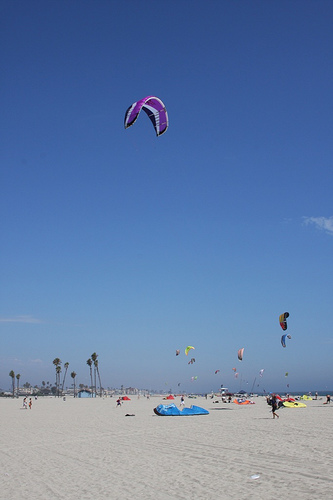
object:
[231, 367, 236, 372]
kites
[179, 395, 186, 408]
person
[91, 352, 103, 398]
tree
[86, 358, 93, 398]
tree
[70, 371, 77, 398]
tree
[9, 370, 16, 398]
tree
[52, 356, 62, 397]
tree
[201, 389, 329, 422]
beach goers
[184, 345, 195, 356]
kite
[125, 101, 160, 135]
stripe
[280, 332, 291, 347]
parasail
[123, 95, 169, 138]
kite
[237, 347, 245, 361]
kites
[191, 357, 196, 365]
kites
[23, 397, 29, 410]
adult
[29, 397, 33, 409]
child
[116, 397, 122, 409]
person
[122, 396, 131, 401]
kite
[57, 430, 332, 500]
tracks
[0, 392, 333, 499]
sand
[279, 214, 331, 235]
white cloud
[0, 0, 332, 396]
blue sky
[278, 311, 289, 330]
parachute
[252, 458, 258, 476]
ground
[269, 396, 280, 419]
people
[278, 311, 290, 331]
kite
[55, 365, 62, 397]
trees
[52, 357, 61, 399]
trees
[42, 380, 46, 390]
trees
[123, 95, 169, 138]
parachute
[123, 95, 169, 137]
para sail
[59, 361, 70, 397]
trees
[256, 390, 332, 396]
ocean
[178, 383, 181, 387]
kites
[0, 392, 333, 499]
beach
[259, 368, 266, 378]
kites